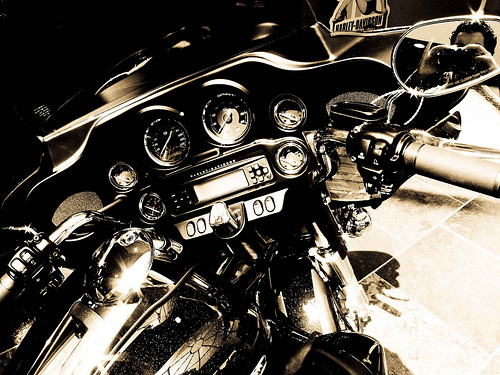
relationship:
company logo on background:
[330, 12, 384, 34] [286, 3, 496, 37]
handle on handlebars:
[2, 233, 70, 308] [326, 104, 498, 222]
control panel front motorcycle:
[114, 79, 313, 226] [14, 25, 481, 365]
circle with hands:
[201, 97, 254, 144] [218, 117, 238, 141]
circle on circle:
[201, 97, 254, 144] [258, 136, 345, 189]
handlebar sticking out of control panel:
[338, 125, 495, 196] [82, 93, 379, 218]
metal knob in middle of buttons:
[203, 191, 239, 240] [161, 205, 322, 243]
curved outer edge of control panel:
[44, 50, 134, 174] [105, 152, 405, 245]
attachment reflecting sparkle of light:
[63, 238, 206, 340] [470, 4, 485, 25]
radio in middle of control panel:
[175, 154, 276, 204] [114, 79, 313, 226]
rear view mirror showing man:
[391, 12, 499, 99] [410, 14, 499, 77]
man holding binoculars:
[410, 14, 499, 77] [424, 39, 461, 65]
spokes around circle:
[139, 325, 242, 372] [201, 97, 254, 144]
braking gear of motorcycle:
[149, 197, 319, 227] [40, 50, 446, 373]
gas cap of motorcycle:
[63, 255, 167, 323] [14, 25, 481, 365]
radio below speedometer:
[175, 154, 276, 204] [131, 107, 311, 154]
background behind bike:
[4, 0, 124, 72] [36, 95, 430, 357]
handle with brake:
[2, 233, 70, 308] [16, 217, 86, 319]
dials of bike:
[91, 88, 358, 231] [21, 48, 404, 373]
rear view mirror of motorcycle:
[391, 12, 499, 99] [14, 25, 481, 365]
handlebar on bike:
[338, 125, 495, 196] [33, 35, 476, 351]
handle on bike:
[2, 233, 70, 308] [33, 35, 476, 351]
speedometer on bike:
[131, 107, 311, 154] [42, 41, 407, 283]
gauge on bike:
[142, 109, 289, 164] [38, 41, 413, 359]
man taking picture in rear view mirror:
[420, 24, 498, 82] [391, 12, 499, 99]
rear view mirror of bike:
[391, 12, 499, 99] [45, 34, 433, 349]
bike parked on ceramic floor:
[58, 68, 447, 369] [361, 177, 499, 375]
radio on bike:
[175, 154, 276, 204] [6, 12, 483, 365]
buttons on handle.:
[247, 162, 266, 183] [54, 78, 465, 219]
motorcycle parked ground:
[36, 19, 469, 373] [395, 247, 483, 373]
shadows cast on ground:
[344, 247, 402, 303] [394, 236, 479, 356]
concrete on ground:
[400, 211, 480, 326] [395, 247, 483, 373]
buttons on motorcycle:
[160, 199, 286, 238] [14, 25, 481, 365]